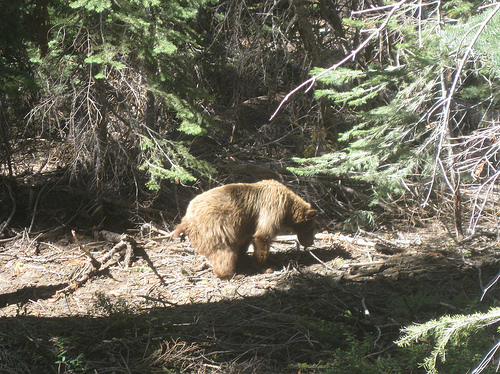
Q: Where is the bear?
A: In the woods.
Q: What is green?
A: Trees.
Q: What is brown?
A: Bear.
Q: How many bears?
A: One.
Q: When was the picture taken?
A: Daytime.